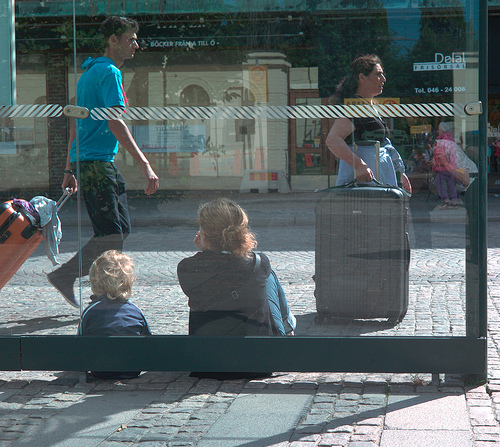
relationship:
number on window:
[400, 80, 464, 97] [356, 23, 405, 49]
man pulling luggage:
[79, 10, 160, 245] [1, 222, 33, 268]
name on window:
[432, 51, 470, 64] [356, 23, 405, 49]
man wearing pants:
[79, 10, 160, 245] [82, 183, 128, 241]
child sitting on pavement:
[71, 242, 146, 371] [152, 219, 188, 244]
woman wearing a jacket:
[202, 269, 257, 321] [242, 262, 272, 295]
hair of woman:
[194, 205, 231, 229] [202, 269, 257, 321]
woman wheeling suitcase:
[202, 269, 257, 321] [305, 183, 412, 318]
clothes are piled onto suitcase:
[22, 203, 59, 222] [305, 183, 412, 318]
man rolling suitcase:
[79, 10, 160, 245] [305, 183, 412, 318]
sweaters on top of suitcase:
[30, 203, 56, 222] [305, 183, 412, 318]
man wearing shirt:
[79, 10, 160, 245] [79, 81, 102, 103]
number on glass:
[400, 80, 464, 97] [314, 3, 372, 31]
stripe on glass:
[189, 90, 265, 120] [314, 3, 372, 31]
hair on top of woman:
[194, 205, 231, 229] [202, 269, 257, 321]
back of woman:
[346, 137, 353, 145] [202, 269, 257, 321]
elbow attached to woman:
[318, 135, 333, 148] [202, 269, 257, 321]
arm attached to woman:
[324, 122, 370, 173] [202, 269, 257, 321]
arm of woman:
[324, 122, 370, 173] [324, 54, 411, 201]